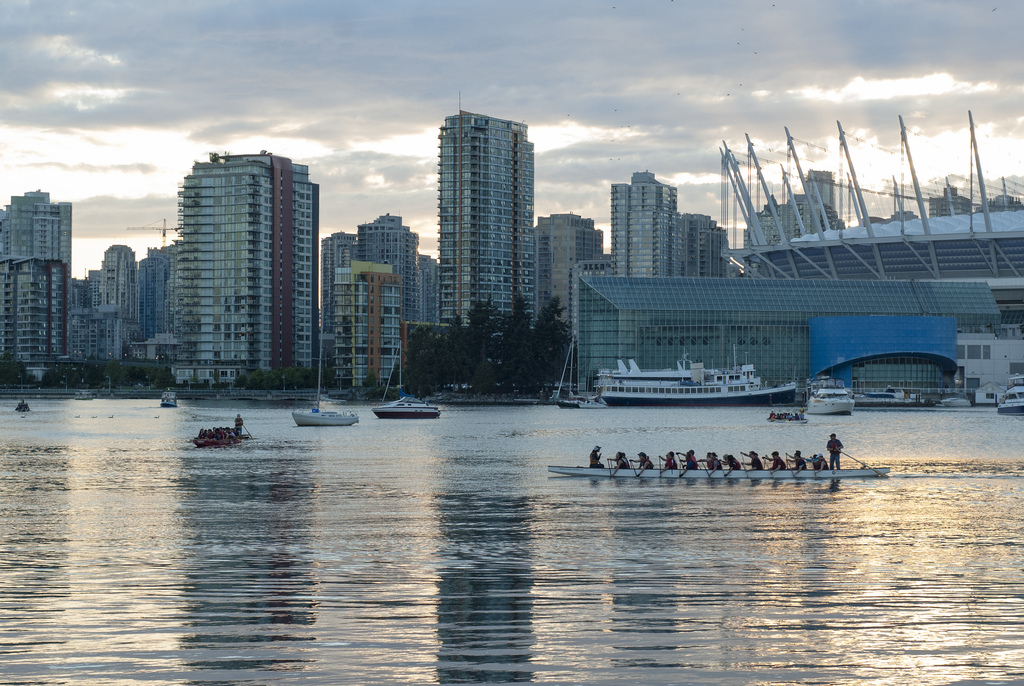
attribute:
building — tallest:
[427, 106, 546, 375]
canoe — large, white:
[538, 455, 910, 484]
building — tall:
[410, 98, 605, 351]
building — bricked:
[291, 199, 464, 439]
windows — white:
[347, 275, 408, 390]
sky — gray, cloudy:
[176, 42, 844, 194]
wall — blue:
[781, 307, 993, 357]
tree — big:
[442, 297, 551, 360]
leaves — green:
[440, 299, 562, 360]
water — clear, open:
[81, 409, 827, 630]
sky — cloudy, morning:
[86, 24, 957, 271]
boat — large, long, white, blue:
[587, 296, 877, 426]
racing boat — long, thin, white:
[524, 441, 903, 502]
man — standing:
[814, 387, 879, 522]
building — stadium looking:
[714, 115, 1021, 414]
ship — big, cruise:
[602, 353, 786, 425]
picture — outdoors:
[10, 10, 1022, 669]